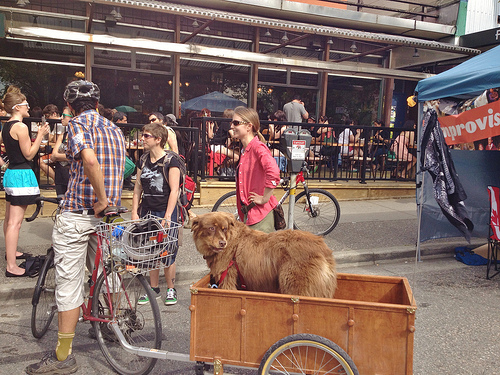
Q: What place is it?
A: It is a restaurant.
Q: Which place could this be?
A: It is a restaurant.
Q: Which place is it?
A: It is a restaurant.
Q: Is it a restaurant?
A: Yes, it is a restaurant.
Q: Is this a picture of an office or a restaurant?
A: It is showing a restaurant.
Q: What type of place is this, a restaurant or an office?
A: It is a restaurant.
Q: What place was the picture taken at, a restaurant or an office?
A: It was taken at a restaurant.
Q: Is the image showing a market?
A: No, the picture is showing a restaurant.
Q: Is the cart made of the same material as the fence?
A: No, the cart is made of wood and the fence is made of metal.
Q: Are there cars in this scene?
A: No, there are no cars.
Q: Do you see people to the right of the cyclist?
A: Yes, there is a person to the right of the cyclist.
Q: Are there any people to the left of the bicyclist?
A: No, the person is to the right of the bicyclist.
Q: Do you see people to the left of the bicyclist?
A: No, the person is to the right of the bicyclist.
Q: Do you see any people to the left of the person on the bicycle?
A: No, the person is to the right of the bicyclist.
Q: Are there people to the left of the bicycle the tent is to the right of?
A: Yes, there is a person to the left of the bicycle.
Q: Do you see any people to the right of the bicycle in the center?
A: No, the person is to the left of the bicycle.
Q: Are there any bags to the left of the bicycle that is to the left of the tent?
A: No, there is a person to the left of the bicycle.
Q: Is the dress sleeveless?
A: Yes, the dress is sleeveless.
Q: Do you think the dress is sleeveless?
A: Yes, the dress is sleeveless.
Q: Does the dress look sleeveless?
A: Yes, the dress is sleeveless.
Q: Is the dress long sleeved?
A: No, the dress is sleeveless.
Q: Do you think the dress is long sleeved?
A: No, the dress is sleeveless.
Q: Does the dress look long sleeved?
A: No, the dress is sleeveless.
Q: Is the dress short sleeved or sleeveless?
A: The dress is sleeveless.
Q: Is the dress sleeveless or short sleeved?
A: The dress is sleeveless.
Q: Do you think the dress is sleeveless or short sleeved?
A: The dress is sleeveless.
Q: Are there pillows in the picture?
A: No, there are no pillows.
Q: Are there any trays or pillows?
A: No, there are no pillows or trays.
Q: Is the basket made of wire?
A: Yes, the basket is made of wire.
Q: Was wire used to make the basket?
A: Yes, the basket is made of wire.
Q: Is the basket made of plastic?
A: No, the basket is made of wire.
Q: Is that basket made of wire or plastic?
A: The basket is made of wire.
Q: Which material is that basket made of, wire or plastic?
A: The basket is made of wire.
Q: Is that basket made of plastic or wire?
A: The basket is made of wire.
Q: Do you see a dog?
A: Yes, there is a dog.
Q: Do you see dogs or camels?
A: Yes, there is a dog.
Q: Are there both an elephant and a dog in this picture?
A: No, there is a dog but no elephants.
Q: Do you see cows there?
A: No, there are no cows.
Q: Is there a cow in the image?
A: No, there are no cows.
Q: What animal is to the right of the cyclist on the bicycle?
A: The animal is a dog.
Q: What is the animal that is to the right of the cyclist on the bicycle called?
A: The animal is a dog.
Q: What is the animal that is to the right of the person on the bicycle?
A: The animal is a dog.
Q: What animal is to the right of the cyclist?
A: The animal is a dog.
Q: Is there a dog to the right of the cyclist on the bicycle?
A: Yes, there is a dog to the right of the cyclist.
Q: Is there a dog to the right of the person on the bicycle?
A: Yes, there is a dog to the right of the cyclist.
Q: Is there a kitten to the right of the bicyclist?
A: No, there is a dog to the right of the bicyclist.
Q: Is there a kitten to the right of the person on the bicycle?
A: No, there is a dog to the right of the bicyclist.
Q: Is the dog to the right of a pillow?
A: No, the dog is to the right of a cyclist.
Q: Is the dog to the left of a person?
A: No, the dog is to the right of a person.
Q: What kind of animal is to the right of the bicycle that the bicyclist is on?
A: The animal is a dog.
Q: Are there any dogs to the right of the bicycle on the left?
A: Yes, there is a dog to the right of the bicycle.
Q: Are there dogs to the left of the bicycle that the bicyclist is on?
A: No, the dog is to the right of the bicycle.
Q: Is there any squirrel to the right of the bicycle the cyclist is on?
A: No, there is a dog to the right of the bicycle.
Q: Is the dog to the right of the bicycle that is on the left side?
A: Yes, the dog is to the right of the bicycle.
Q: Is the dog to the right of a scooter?
A: No, the dog is to the right of the bicycle.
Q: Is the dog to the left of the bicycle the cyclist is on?
A: No, the dog is to the right of the bicycle.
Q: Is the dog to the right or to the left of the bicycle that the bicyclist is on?
A: The dog is to the right of the bicycle.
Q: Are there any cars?
A: No, there are no cars.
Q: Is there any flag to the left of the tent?
A: No, there is a person to the left of the tent.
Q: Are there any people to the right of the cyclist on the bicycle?
A: Yes, there is a person to the right of the cyclist.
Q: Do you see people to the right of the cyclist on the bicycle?
A: Yes, there is a person to the right of the cyclist.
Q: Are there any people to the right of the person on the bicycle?
A: Yes, there is a person to the right of the cyclist.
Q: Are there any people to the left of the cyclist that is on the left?
A: No, the person is to the right of the bicyclist.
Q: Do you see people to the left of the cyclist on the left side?
A: No, the person is to the right of the bicyclist.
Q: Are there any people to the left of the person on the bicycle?
A: No, the person is to the right of the bicyclist.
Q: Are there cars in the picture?
A: No, there are no cars.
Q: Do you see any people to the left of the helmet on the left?
A: Yes, there is a person to the left of the helmet.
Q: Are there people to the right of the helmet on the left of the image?
A: No, the person is to the left of the helmet.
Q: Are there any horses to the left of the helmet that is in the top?
A: No, there is a person to the left of the helmet.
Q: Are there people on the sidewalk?
A: Yes, there is a person on the sidewalk.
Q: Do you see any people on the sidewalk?
A: Yes, there is a person on the sidewalk.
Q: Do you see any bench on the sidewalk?
A: No, there is a person on the sidewalk.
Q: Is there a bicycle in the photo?
A: Yes, there is a bicycle.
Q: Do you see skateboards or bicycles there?
A: Yes, there is a bicycle.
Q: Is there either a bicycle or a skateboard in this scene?
A: Yes, there is a bicycle.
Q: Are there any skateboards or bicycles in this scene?
A: Yes, there is a bicycle.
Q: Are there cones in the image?
A: No, there are no cones.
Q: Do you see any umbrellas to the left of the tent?
A: No, there is a bicycle to the left of the tent.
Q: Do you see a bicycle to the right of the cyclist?
A: Yes, there is a bicycle to the right of the cyclist.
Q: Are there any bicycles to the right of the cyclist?
A: Yes, there is a bicycle to the right of the cyclist.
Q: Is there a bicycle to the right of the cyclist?
A: Yes, there is a bicycle to the right of the cyclist.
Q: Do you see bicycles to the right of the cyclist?
A: Yes, there is a bicycle to the right of the cyclist.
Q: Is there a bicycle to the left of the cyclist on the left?
A: No, the bicycle is to the right of the cyclist.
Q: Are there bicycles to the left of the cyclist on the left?
A: No, the bicycle is to the right of the cyclist.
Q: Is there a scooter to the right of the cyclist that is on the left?
A: No, there is a bicycle to the right of the cyclist.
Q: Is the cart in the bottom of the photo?
A: Yes, the cart is in the bottom of the image.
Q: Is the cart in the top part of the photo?
A: No, the cart is in the bottom of the image.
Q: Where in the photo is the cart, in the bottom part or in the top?
A: The cart is in the bottom of the image.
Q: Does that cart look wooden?
A: Yes, the cart is wooden.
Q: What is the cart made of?
A: The cart is made of wood.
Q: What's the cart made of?
A: The cart is made of wood.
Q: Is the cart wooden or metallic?
A: The cart is wooden.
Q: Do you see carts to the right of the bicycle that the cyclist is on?
A: Yes, there is a cart to the right of the bicycle.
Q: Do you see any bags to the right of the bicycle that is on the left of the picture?
A: No, there is a cart to the right of the bicycle.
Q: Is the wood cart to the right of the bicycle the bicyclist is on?
A: Yes, the cart is to the right of the bicycle.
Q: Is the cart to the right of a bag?
A: No, the cart is to the right of the bicycle.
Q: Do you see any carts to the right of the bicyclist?
A: Yes, there is a cart to the right of the bicyclist.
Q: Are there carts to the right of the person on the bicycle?
A: Yes, there is a cart to the right of the bicyclist.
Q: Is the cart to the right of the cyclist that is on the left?
A: Yes, the cart is to the right of the bicyclist.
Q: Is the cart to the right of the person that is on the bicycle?
A: Yes, the cart is to the right of the bicyclist.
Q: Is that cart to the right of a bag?
A: No, the cart is to the right of the bicyclist.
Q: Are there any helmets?
A: Yes, there is a helmet.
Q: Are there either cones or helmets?
A: Yes, there is a helmet.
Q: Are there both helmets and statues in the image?
A: No, there is a helmet but no statues.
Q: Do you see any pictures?
A: No, there are no pictures.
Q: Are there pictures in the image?
A: No, there are no pictures.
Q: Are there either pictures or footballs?
A: No, there are no pictures or footballs.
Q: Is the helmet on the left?
A: Yes, the helmet is on the left of the image.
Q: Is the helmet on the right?
A: No, the helmet is on the left of the image.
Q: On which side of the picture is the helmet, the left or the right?
A: The helmet is on the left of the image.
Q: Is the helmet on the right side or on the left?
A: The helmet is on the left of the image.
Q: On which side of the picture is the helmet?
A: The helmet is on the left of the image.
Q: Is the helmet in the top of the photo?
A: Yes, the helmet is in the top of the image.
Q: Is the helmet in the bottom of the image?
A: No, the helmet is in the top of the image.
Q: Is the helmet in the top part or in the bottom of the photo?
A: The helmet is in the top of the image.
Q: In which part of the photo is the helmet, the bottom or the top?
A: The helmet is in the top of the image.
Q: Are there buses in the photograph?
A: No, there are no buses.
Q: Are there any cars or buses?
A: No, there are no buses or cars.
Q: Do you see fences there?
A: Yes, there is a fence.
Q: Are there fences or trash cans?
A: Yes, there is a fence.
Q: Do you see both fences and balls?
A: No, there is a fence but no balls.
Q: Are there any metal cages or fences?
A: Yes, there is a metal fence.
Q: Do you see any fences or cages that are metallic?
A: Yes, the fence is metallic.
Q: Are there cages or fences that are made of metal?
A: Yes, the fence is made of metal.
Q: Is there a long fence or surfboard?
A: Yes, there is a long fence.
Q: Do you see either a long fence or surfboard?
A: Yes, there is a long fence.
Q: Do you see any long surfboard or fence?
A: Yes, there is a long fence.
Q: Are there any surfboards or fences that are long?
A: Yes, the fence is long.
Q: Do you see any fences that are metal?
A: Yes, there is a metal fence.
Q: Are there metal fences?
A: Yes, there is a metal fence.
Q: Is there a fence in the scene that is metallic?
A: Yes, there is a fence that is metallic.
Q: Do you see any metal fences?
A: Yes, there is a fence that is made of metal.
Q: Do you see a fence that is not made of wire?
A: Yes, there is a fence that is made of metal.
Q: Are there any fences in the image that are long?
A: Yes, there is a long fence.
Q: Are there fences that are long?
A: Yes, there is a fence that is long.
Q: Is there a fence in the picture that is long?
A: Yes, there is a fence that is long.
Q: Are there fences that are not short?
A: Yes, there is a long fence.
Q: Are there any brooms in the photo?
A: No, there are no brooms.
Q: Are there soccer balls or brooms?
A: No, there are no brooms or soccer balls.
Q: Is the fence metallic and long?
A: Yes, the fence is metallic and long.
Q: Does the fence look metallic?
A: Yes, the fence is metallic.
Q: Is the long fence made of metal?
A: Yes, the fence is made of metal.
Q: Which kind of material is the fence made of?
A: The fence is made of metal.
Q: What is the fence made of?
A: The fence is made of metal.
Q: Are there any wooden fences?
A: No, there is a fence but it is metallic.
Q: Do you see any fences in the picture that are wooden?
A: No, there is a fence but it is metallic.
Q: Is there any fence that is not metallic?
A: No, there is a fence but it is metallic.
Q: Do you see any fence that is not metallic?
A: No, there is a fence but it is metallic.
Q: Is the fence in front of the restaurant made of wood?
A: No, the fence is made of metal.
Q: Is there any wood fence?
A: No, there is a fence but it is made of metal.